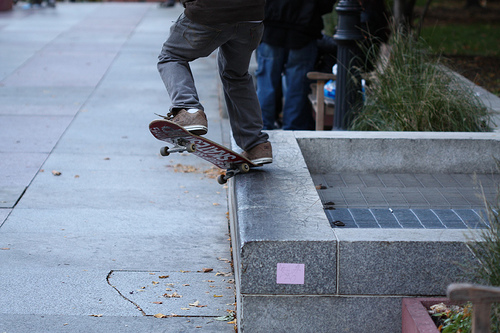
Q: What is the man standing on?
A: Skateboard.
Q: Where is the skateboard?
A: On a short wall.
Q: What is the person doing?
A: Skateboarding.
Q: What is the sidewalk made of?
A: Cement.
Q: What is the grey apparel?
A: Skater's pants.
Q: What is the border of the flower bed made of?
A: Bricks.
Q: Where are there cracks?
A: In the sidewalk.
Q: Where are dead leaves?
A: On the sidewalk.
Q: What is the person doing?
A: Skateboarding.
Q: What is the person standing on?
A: Skateboard.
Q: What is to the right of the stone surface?
A: Metal vent.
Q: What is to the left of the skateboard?
A: Sidewalk.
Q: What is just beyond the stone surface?
A: Patch of tall grass.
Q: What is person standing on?
A: Skateboard.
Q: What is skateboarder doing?
A: Skateboarding on wall.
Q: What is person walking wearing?
A: Blue jeans.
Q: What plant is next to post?
A: Decorative grass.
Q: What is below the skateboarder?
A: A sidewalk.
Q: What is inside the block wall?
A: A grate.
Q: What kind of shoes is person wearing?
A: Tennis shoes.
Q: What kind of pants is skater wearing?
A: Gray jeans.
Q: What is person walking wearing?
A: A black shirt.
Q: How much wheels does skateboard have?
A: Four.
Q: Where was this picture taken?
A: In a city.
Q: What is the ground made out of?
A: Concrete.